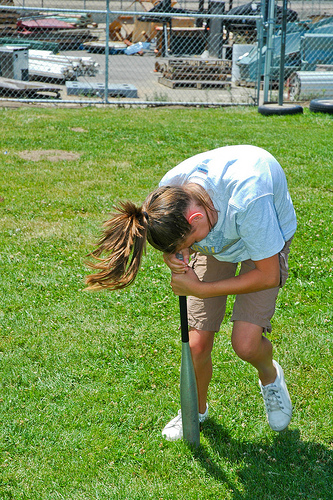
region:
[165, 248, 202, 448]
a silver and black baseball bat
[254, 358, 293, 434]
a white shoe on a woman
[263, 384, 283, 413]
a shoestring on the shoe of a woman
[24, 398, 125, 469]
the green grass on the ground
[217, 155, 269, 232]
a gray and white t-shirt on a woman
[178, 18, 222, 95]
a silver chain linked fence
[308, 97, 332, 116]
a black tire laying in the grass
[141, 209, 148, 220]
a black rubber band in the woman's hair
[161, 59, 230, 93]
a stack of wooden pallets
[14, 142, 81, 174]
a patch of dirt in the grass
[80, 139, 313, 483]
Girl bent over the bat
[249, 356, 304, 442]
Girl wearing white sneakers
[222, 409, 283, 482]
Shadow in the grass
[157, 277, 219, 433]
Baseball bat made of metal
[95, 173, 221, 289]
Little girl has a ponytail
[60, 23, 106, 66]
Chain link fence in background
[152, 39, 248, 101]
Pile of trash behind fence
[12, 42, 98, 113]
Metal stacked in a pile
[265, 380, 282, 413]
White shoelaces on the shoe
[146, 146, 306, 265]
Short sleeve tshirt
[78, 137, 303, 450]
woman holding a baseball bat to her forehead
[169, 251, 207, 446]
bat is silver and black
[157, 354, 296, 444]
woman wearing white shoes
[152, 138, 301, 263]
woman wearing a grey shirt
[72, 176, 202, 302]
woman's hair is pulled into a ponytail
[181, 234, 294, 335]
woman wearing light brown shorts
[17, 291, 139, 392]
grass on the ground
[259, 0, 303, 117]
pole embedded in a tire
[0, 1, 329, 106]
chain-link fence with gate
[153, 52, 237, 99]
pallets stacked behind fence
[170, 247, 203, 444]
green baseball bat with black handle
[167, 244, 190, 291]
girl's two hands wrapped around baseball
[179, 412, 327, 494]
shadow of girl on grass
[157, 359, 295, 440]
white sneakers with white laces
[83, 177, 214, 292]
girl's ponytail hangs off to side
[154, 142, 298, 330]
light T-shirt and khakis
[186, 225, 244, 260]
gray and yellow design on T-shirt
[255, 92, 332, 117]
two spare tires on grass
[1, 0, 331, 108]
chain-link fence behind grass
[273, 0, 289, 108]
metal pole on spare tire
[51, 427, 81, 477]
the grass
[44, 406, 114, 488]
the grass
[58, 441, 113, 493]
the grass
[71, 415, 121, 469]
the grass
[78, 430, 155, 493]
the grass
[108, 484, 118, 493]
the grass